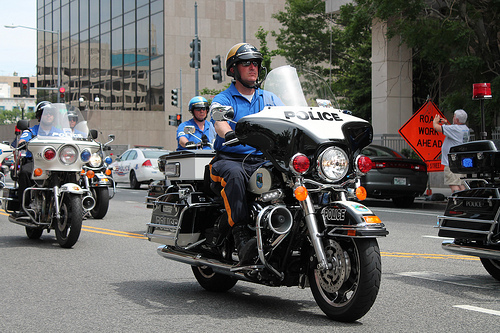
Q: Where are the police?
A: Bikes.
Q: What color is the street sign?
A: Orange.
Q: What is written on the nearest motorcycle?
A: Police.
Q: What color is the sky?
A: Blue.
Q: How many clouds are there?
A: None.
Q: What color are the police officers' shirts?
A: Blue.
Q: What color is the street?
A: Gray.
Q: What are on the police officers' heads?
A: Helmets.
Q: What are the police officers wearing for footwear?
A: Boots.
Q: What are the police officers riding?
A: Motorcycles.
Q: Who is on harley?
A: Police officer.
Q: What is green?
A: Trees in background.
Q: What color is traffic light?
A: Red.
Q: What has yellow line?
A: Street.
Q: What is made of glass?
A: Building.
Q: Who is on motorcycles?
A: Couple of police.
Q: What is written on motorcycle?
A: Police.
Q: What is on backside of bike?
A: Storage area.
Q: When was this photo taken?
A: During the daytime.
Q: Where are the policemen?
A: Riding motorcycles.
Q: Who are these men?
A: Police.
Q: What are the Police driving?
A: Motorcycle.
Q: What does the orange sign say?
A: Road Work Ahead.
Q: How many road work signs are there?
A: 1.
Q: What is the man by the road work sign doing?
A: Taking a picture.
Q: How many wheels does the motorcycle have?
A: Two.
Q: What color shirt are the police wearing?
A: Blue.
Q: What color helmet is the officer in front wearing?
A: Gold.